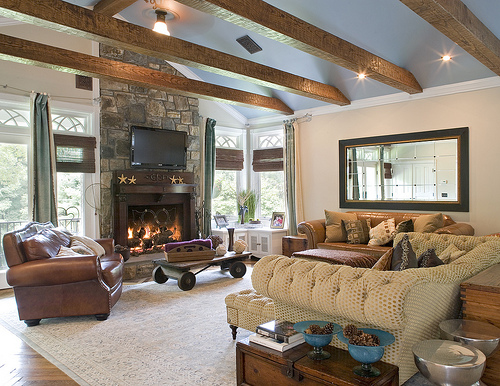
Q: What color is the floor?
A: Brown.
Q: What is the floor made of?
A: Wood.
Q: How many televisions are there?
A: One.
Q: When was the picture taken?
A: Daytime.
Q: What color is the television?
A: Black.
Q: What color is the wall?
A: White.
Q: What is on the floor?
A: The rug.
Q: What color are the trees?
A: Green.